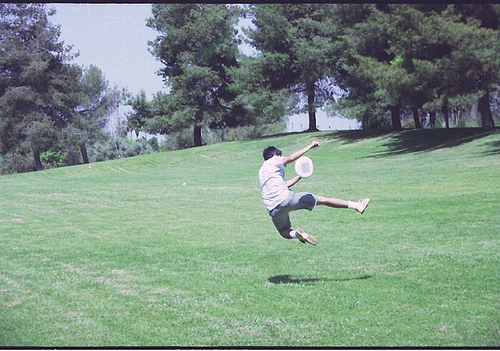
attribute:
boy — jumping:
[263, 133, 350, 244]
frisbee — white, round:
[294, 157, 316, 179]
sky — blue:
[101, 9, 144, 57]